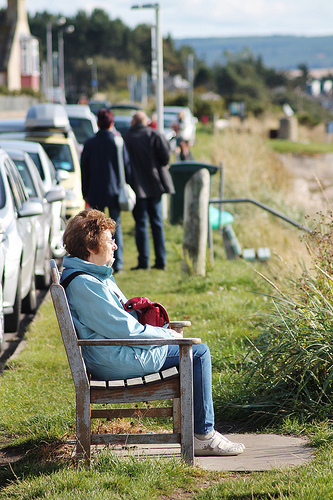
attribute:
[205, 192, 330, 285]
metal railing — gray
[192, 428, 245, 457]
velcro sneakers — strapped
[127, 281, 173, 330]
purse — red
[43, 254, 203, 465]
bench — old, wood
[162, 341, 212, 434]
jeans — blue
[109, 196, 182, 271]
jeans — blue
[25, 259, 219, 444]
bench — light grey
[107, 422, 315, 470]
cement — gray 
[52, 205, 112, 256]
hair — brown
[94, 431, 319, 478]
concrete — grey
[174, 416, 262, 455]
shoes — white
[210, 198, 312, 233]
pipe — round, metal, railing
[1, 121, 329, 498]
hill — seated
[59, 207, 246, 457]
lady — sitting, old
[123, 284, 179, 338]
purse — red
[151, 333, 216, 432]
pants — blue, jeans, long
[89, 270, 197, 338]
bag — red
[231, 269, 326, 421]
bush — green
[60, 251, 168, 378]
jacket — long sleeved, warm, blue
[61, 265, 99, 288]
jacket trim — dark blue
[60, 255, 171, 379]
coat — blue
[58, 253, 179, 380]
jacket — blue